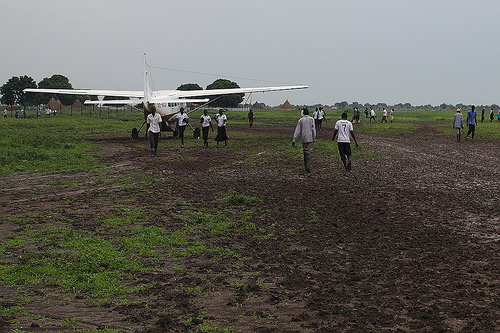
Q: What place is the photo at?
A: It is at the field.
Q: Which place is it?
A: It is a field.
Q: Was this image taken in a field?
A: Yes, it was taken in a field.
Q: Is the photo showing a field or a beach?
A: It is showing a field.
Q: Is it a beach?
A: No, it is a field.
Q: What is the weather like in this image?
A: It is cloudy.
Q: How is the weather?
A: It is cloudy.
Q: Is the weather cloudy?
A: Yes, it is cloudy.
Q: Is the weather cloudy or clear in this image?
A: It is cloudy.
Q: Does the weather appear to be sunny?
A: No, it is cloudy.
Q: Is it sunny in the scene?
A: No, it is cloudy.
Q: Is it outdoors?
A: Yes, it is outdoors.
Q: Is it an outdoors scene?
A: Yes, it is outdoors.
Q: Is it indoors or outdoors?
A: It is outdoors.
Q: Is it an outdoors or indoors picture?
A: It is outdoors.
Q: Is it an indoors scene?
A: No, it is outdoors.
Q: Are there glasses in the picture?
A: No, there are no glasses.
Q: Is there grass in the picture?
A: Yes, there is grass.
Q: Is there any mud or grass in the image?
A: Yes, there is grass.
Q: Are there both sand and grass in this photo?
A: No, there is grass but no sand.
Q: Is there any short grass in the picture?
A: Yes, there is short grass.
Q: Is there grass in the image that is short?
A: Yes, there is grass that is short.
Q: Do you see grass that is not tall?
A: Yes, there is short grass.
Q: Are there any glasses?
A: No, there are no glasses.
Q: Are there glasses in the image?
A: No, there are no glasses.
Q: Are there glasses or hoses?
A: No, there are no glasses or hoses.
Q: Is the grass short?
A: Yes, the grass is short.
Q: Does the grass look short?
A: Yes, the grass is short.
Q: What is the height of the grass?
A: The grass is short.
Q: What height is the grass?
A: The grass is short.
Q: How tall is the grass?
A: The grass is short.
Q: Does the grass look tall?
A: No, the grass is short.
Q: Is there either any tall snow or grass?
A: No, there is grass but it is short.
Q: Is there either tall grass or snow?
A: No, there is grass but it is short.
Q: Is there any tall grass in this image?
A: No, there is grass but it is short.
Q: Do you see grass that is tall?
A: No, there is grass but it is short.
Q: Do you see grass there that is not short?
A: No, there is grass but it is short.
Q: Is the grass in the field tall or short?
A: The grass is short.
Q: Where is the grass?
A: The grass is in the field.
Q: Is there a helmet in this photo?
A: No, there are no helmets.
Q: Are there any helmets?
A: No, there are no helmets.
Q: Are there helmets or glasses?
A: No, there are no helmets or glasses.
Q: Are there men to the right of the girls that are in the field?
A: Yes, there is a man to the right of the girls.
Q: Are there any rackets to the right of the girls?
A: No, there is a man to the right of the girls.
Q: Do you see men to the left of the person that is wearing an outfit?
A: Yes, there is a man to the left of the person.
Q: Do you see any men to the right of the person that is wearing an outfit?
A: No, the man is to the left of the person.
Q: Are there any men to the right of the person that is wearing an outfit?
A: No, the man is to the left of the person.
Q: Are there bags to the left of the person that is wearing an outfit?
A: No, there is a man to the left of the person.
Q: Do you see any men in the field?
A: Yes, there is a man in the field.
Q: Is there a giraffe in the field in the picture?
A: No, there is a man in the field.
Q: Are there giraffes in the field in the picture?
A: No, there is a man in the field.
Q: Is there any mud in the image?
A: Yes, there is mud.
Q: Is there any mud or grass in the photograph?
A: Yes, there is mud.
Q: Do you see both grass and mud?
A: Yes, there are both mud and grass.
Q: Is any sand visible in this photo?
A: No, there is no sand.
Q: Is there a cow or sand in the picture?
A: No, there are no sand or cows.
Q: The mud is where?
A: The mud is on the field.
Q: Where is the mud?
A: The mud is on the field.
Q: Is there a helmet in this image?
A: No, there are no helmets.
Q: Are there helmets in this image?
A: No, there are no helmets.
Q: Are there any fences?
A: Yes, there is a fence.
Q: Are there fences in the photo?
A: Yes, there is a fence.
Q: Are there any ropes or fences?
A: Yes, there is a fence.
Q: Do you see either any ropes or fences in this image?
A: Yes, there is a fence.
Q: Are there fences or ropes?
A: Yes, there is a fence.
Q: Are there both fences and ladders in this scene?
A: No, there is a fence but no ladders.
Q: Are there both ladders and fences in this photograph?
A: No, there is a fence but no ladders.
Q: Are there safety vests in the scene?
A: No, there are no safety vests.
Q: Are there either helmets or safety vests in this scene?
A: No, there are no safety vests or helmets.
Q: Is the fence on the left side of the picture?
A: Yes, the fence is on the left of the image.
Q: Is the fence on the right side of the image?
A: No, the fence is on the left of the image.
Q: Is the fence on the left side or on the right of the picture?
A: The fence is on the left of the image.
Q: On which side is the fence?
A: The fence is on the left of the image.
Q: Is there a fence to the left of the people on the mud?
A: Yes, there is a fence to the left of the people.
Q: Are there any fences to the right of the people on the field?
A: No, the fence is to the left of the people.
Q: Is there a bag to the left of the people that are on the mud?
A: No, there is a fence to the left of the people.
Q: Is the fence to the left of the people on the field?
A: Yes, the fence is to the left of the people.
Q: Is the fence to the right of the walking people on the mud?
A: No, the fence is to the left of the people.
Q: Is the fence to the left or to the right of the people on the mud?
A: The fence is to the left of the people.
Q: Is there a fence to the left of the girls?
A: Yes, there is a fence to the left of the girls.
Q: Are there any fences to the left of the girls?
A: Yes, there is a fence to the left of the girls.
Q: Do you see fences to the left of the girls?
A: Yes, there is a fence to the left of the girls.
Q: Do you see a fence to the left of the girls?
A: Yes, there is a fence to the left of the girls.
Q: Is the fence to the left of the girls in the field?
A: Yes, the fence is to the left of the girls.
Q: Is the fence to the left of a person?
A: Yes, the fence is to the left of a person.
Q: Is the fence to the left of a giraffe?
A: No, the fence is to the left of a person.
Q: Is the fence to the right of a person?
A: No, the fence is to the left of a person.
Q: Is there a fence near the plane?
A: Yes, there is a fence near the plane.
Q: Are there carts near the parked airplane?
A: No, there is a fence near the plane.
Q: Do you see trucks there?
A: No, there are no trucks.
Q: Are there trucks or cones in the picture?
A: No, there are no trucks or cones.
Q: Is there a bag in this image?
A: No, there are no bags.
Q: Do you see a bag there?
A: No, there are no bags.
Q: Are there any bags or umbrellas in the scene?
A: No, there are no bags or umbrellas.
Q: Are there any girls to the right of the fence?
A: Yes, there are girls to the right of the fence.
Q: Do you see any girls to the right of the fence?
A: Yes, there are girls to the right of the fence.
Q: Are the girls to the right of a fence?
A: Yes, the girls are to the right of a fence.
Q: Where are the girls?
A: The girls are in the field.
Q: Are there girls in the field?
A: Yes, there are girls in the field.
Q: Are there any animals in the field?
A: No, there are girls in the field.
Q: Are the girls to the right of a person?
A: No, the girls are to the left of a person.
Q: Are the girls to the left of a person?
A: No, the girls are to the right of a person.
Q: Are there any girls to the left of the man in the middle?
A: Yes, there are girls to the left of the man.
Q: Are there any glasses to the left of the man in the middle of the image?
A: No, there are girls to the left of the man.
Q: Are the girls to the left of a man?
A: Yes, the girls are to the left of a man.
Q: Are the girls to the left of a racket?
A: No, the girls are to the left of a man.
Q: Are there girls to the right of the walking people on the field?
A: Yes, there are girls to the right of the people.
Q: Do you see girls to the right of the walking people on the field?
A: Yes, there are girls to the right of the people.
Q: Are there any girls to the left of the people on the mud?
A: No, the girls are to the right of the people.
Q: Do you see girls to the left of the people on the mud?
A: No, the girls are to the right of the people.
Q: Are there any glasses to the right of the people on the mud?
A: No, there are girls to the right of the people.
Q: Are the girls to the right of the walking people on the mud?
A: Yes, the girls are to the right of the people.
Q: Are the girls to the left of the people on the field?
A: No, the girls are to the right of the people.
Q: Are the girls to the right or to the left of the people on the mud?
A: The girls are to the right of the people.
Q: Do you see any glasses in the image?
A: No, there are no glasses.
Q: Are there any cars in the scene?
A: No, there are no cars.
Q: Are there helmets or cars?
A: No, there are no cars or helmets.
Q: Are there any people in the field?
A: Yes, there is a person in the field.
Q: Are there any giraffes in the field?
A: No, there is a person in the field.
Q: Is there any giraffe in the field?
A: No, there is a person in the field.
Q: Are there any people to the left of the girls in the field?
A: Yes, there is a person to the left of the girls.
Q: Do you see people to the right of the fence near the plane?
A: Yes, there is a person to the right of the fence.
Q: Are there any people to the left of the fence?
A: No, the person is to the right of the fence.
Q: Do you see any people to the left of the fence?
A: No, the person is to the right of the fence.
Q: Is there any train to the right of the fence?
A: No, there is a person to the right of the fence.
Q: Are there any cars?
A: No, there are no cars.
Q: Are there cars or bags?
A: No, there are no cars or bags.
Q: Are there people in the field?
A: Yes, there is a person in the field.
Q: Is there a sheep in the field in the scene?
A: No, there is a person in the field.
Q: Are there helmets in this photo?
A: No, there are no helmets.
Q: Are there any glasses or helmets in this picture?
A: No, there are no helmets or glasses.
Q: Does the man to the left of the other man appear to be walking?
A: Yes, the man is walking.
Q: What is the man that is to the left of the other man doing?
A: The man is walking.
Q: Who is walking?
A: The man is walking.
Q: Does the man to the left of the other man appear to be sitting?
A: No, the man is walking.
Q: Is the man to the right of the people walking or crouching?
A: The man is walking.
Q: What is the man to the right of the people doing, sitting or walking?
A: The man is walking.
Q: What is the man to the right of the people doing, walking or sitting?
A: The man is walking.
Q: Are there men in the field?
A: Yes, there is a man in the field.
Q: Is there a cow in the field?
A: No, there is a man in the field.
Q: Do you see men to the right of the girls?
A: Yes, there is a man to the right of the girls.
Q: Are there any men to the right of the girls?
A: Yes, there is a man to the right of the girls.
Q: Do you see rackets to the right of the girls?
A: No, there is a man to the right of the girls.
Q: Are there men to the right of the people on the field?
A: Yes, there is a man to the right of the people.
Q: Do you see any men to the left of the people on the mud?
A: No, the man is to the right of the people.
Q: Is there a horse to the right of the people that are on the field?
A: No, there is a man to the right of the people.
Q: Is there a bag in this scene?
A: No, there are no bags.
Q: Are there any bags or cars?
A: No, there are no bags or cars.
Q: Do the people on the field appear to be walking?
A: Yes, the people are walking.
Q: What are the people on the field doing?
A: The people are walking.